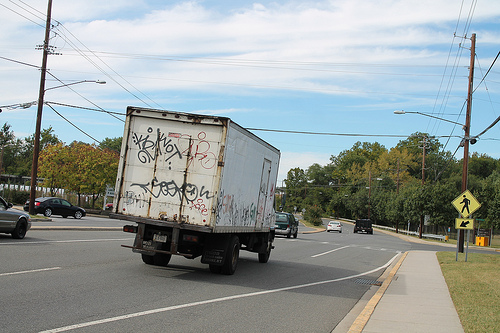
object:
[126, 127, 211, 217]
graffiti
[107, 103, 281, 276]
truck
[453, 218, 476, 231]
sign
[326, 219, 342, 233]
car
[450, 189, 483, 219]
sign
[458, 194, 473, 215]
figure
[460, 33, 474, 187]
pole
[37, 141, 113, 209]
tree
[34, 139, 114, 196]
leaves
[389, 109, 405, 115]
streetlight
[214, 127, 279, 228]
side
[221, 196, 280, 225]
graffiti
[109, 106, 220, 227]
back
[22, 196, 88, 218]
car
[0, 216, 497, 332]
road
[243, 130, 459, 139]
power lines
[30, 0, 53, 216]
pole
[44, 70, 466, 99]
powerlines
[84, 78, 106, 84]
streetlight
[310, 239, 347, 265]
line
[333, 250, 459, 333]
sidewalk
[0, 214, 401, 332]
crosswalk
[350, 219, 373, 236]
car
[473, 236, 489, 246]
object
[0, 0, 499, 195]
sky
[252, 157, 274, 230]
door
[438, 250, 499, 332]
grass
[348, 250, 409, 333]
curb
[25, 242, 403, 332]
line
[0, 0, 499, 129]
clouds